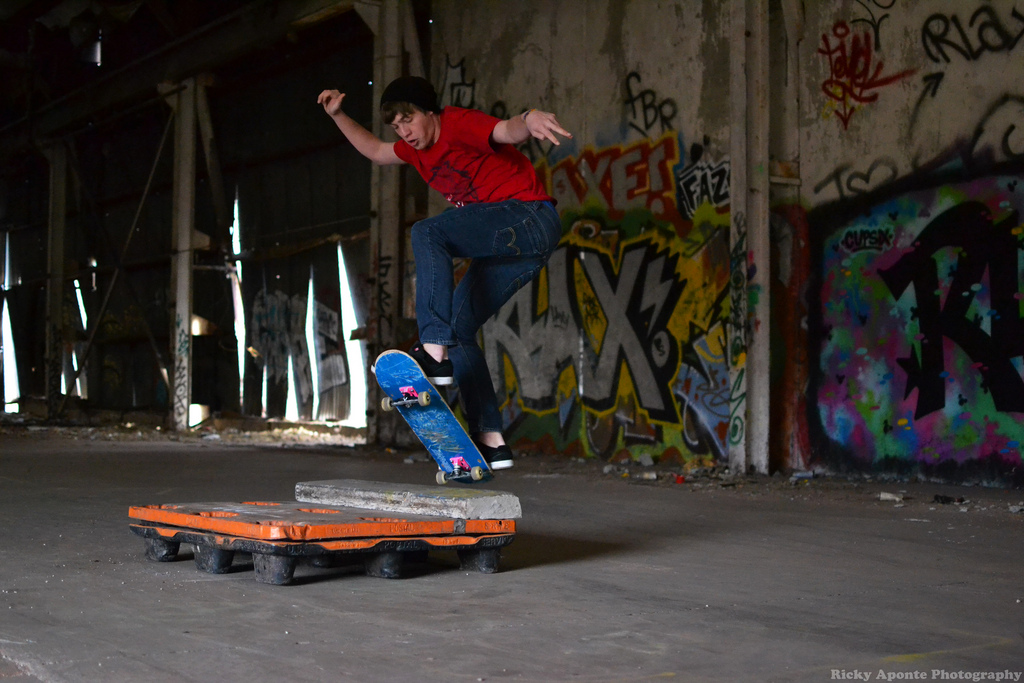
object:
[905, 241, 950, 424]
black graffiti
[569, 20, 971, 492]
wall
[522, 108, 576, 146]
hand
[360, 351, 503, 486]
skateboard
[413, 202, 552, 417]
jeans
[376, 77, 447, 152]
person's head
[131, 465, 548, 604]
pallet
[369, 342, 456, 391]
shoe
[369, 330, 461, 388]
foot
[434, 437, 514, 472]
shoe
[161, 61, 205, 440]
pole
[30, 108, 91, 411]
pole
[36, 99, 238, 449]
door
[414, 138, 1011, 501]
graffiti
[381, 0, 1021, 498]
wall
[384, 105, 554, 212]
red shirt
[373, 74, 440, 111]
black hat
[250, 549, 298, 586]
wheels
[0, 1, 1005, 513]
wall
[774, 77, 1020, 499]
graffiti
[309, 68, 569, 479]
boy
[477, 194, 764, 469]
graphiti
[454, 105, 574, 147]
man's arm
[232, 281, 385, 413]
graphiti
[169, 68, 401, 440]
door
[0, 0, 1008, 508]
building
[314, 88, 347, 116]
hand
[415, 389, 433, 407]
wheel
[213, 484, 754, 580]
shadow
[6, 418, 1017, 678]
ground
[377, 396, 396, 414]
wheel